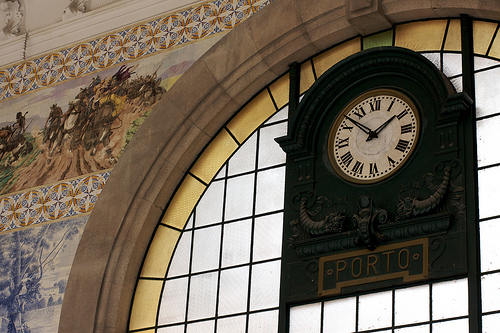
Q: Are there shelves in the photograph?
A: No, there are no shelves.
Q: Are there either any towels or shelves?
A: No, there are no shelves or towels.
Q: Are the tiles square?
A: Yes, the tiles are square.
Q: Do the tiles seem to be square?
A: Yes, the tiles are square.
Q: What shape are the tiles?
A: The tiles are square.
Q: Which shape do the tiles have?
A: The tiles have square shape.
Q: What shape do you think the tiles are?
A: The tiles are square.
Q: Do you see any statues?
A: No, there are no statues.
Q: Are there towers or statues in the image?
A: No, there are no statues or towers.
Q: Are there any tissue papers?
A: No, there are no tissue papers.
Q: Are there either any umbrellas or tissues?
A: No, there are no tissues or umbrellas.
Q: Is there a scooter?
A: No, there are no scooters.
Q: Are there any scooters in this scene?
A: No, there are no scooters.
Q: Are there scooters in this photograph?
A: No, there are no scooters.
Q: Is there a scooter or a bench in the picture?
A: No, there are no scooters or benches.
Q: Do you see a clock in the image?
A: Yes, there is a clock.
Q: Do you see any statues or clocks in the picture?
A: Yes, there is a clock.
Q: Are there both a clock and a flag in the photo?
A: No, there is a clock but no flags.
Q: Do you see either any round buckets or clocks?
A: Yes, there is a round clock.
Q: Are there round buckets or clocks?
A: Yes, there is a round clock.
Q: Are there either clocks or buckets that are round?
A: Yes, the clock is round.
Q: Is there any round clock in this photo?
A: Yes, there is a round clock.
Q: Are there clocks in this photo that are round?
A: Yes, there is a clock that is round.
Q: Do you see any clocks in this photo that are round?
A: Yes, there is a clock that is round.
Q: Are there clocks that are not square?
A: Yes, there is a round clock.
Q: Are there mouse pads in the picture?
A: No, there are no mouse pads.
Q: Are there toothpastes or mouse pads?
A: No, there are no mouse pads or toothpastes.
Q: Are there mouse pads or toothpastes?
A: No, there are no mouse pads or toothpastes.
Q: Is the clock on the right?
A: Yes, the clock is on the right of the image.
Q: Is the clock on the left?
A: No, the clock is on the right of the image.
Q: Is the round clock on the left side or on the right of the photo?
A: The clock is on the right of the image.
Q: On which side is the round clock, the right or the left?
A: The clock is on the right of the image.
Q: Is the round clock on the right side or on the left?
A: The clock is on the right of the image.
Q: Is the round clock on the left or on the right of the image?
A: The clock is on the right of the image.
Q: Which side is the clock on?
A: The clock is on the right of the image.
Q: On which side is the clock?
A: The clock is on the right of the image.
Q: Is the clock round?
A: Yes, the clock is round.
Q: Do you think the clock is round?
A: Yes, the clock is round.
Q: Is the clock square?
A: No, the clock is round.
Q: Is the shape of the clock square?
A: No, the clock is round.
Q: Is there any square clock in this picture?
A: No, there is a clock but it is round.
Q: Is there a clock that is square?
A: No, there is a clock but it is round.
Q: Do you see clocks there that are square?
A: No, there is a clock but it is round.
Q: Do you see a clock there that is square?
A: No, there is a clock but it is round.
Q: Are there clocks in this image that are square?
A: No, there is a clock but it is round.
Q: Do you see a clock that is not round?
A: No, there is a clock but it is round.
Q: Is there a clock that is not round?
A: No, there is a clock but it is round.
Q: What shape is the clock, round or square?
A: The clock is round.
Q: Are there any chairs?
A: No, there are no chairs.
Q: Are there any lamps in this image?
A: No, there are no lamps.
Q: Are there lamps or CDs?
A: No, there are no lamps or cds.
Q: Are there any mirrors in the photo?
A: No, there are no mirrors.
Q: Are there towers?
A: No, there are no towers.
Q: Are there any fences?
A: No, there are no fences.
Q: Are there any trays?
A: No, there are no trays.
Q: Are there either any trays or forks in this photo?
A: No, there are no trays or forks.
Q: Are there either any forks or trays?
A: No, there are no trays or forks.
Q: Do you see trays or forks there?
A: No, there are no trays or forks.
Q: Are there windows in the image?
A: Yes, there is a window.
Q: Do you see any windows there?
A: Yes, there is a window.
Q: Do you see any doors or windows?
A: Yes, there is a window.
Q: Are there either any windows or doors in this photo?
A: Yes, there is a window.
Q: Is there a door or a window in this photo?
A: Yes, there is a window.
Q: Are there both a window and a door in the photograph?
A: No, there is a window but no doors.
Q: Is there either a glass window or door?
A: Yes, there is a glass window.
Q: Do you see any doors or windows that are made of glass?
A: Yes, the window is made of glass.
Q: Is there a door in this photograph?
A: No, there are no doors.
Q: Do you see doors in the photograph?
A: No, there are no doors.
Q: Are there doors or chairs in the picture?
A: No, there are no doors or chairs.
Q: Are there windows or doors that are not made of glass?
A: No, there is a window but it is made of glass.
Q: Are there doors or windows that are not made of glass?
A: No, there is a window but it is made of glass.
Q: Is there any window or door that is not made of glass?
A: No, there is a window but it is made of glass.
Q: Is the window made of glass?
A: Yes, the window is made of glass.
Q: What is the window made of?
A: The window is made of glass.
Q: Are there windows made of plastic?
A: No, there is a window but it is made of glass.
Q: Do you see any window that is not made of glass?
A: No, there is a window but it is made of glass.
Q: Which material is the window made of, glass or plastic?
A: The window is made of glass.